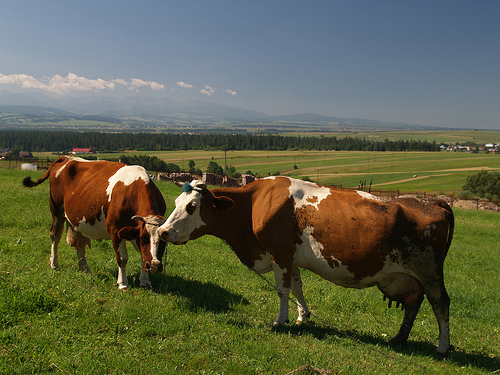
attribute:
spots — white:
[286, 180, 333, 211]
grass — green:
[5, 239, 302, 373]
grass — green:
[449, 216, 497, 364]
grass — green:
[302, 289, 447, 361]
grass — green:
[470, 240, 494, 255]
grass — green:
[7, 213, 37, 268]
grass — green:
[23, 291, 58, 336]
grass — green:
[163, 303, 210, 335]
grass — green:
[346, 320, 368, 348]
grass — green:
[21, 287, 277, 367]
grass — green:
[9, 298, 234, 373]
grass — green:
[130, 300, 207, 355]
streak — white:
[143, 212, 162, 265]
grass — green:
[60, 295, 364, 357]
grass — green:
[0, 152, 495, 374]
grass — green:
[1, 283, 61, 315]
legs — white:
[257, 250, 320, 336]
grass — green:
[2, 180, 497, 373]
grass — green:
[53, 282, 223, 373]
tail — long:
[19, 153, 71, 193]